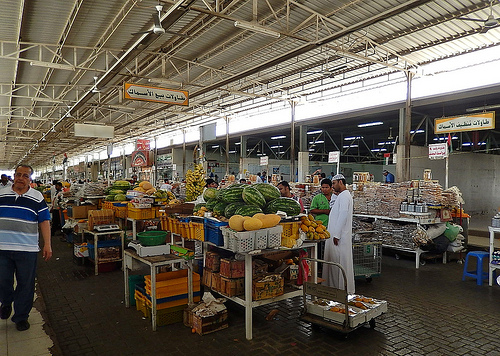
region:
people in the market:
[15, 150, 413, 332]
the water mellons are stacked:
[197, 180, 306, 215]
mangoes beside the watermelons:
[299, 214, 333, 242]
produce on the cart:
[308, 285, 385, 320]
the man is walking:
[7, 151, 67, 331]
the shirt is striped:
[0, 184, 57, 264]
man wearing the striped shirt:
[1, 178, 58, 263]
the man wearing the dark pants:
[0, 248, 46, 314]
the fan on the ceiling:
[127, 13, 200, 48]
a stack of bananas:
[174, 161, 214, 207]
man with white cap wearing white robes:
[321, 172, 356, 292]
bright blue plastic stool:
[457, 250, 490, 292]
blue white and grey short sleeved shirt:
[0, 187, 50, 252]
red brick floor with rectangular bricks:
[400, 311, 494, 350]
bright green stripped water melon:
[206, 182, 300, 212]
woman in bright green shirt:
[308, 179, 334, 226]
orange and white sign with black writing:
[117, 82, 191, 107]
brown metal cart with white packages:
[295, 252, 390, 337]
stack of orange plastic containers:
[143, 267, 201, 299]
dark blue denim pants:
[0, 247, 40, 329]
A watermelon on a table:
[267, 195, 304, 217]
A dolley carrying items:
[300, 258, 385, 335]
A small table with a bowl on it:
[121, 243, 196, 329]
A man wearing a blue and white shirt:
[0, 163, 53, 328]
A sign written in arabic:
[121, 83, 189, 103]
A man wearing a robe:
[325, 173, 358, 292]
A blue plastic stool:
[462, 248, 492, 287]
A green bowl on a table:
[134, 229, 170, 244]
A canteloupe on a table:
[227, 213, 246, 230]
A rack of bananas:
[187, 163, 206, 200]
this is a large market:
[4, 1, 497, 350]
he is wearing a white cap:
[311, 166, 383, 310]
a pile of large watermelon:
[190, 175, 305, 222]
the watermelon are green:
[201, 174, 321, 224]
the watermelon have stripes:
[195, 169, 311, 220]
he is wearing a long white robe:
[313, 155, 377, 320]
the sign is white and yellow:
[108, 75, 216, 110]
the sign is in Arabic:
[108, 73, 216, 116]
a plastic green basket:
[133, 224, 178, 246]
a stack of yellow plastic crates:
[123, 269, 210, 337]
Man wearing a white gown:
[322, 171, 359, 300]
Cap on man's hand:
[331, 170, 348, 186]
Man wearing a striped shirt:
[1, 161, 58, 338]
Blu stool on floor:
[457, 241, 492, 288]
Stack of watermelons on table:
[195, 180, 305, 225]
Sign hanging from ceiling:
[112, 72, 197, 111]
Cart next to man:
[295, 249, 395, 340]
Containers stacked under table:
[127, 262, 222, 337]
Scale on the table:
[122, 221, 174, 262]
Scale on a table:
[91, 219, 128, 236]